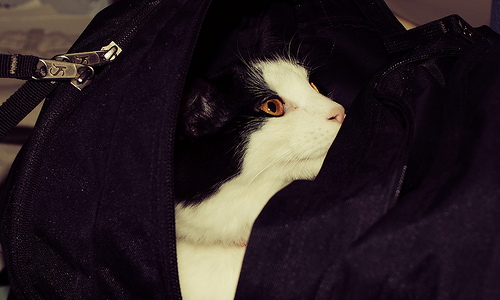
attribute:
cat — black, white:
[171, 41, 346, 299]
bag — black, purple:
[2, 1, 498, 298]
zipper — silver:
[0, 1, 164, 298]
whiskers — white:
[234, 138, 326, 182]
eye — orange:
[252, 94, 286, 118]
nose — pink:
[326, 104, 345, 123]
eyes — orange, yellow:
[257, 80, 320, 117]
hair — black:
[173, 47, 297, 209]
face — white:
[222, 57, 346, 181]